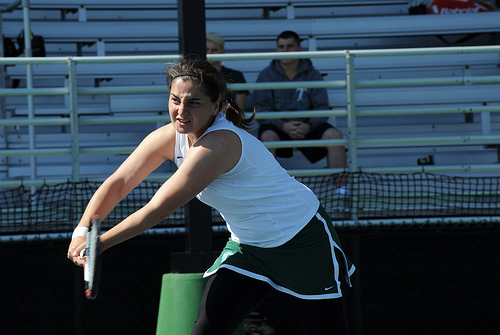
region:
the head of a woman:
[154, 50, 219, 137]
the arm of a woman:
[100, 128, 235, 250]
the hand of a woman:
[63, 225, 94, 265]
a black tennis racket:
[68, 200, 112, 299]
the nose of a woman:
[174, 97, 190, 119]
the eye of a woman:
[168, 92, 183, 106]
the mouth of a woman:
[173, 110, 195, 128]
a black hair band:
[164, 67, 226, 94]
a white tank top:
[169, 110, 329, 252]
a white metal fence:
[1, 40, 498, 225]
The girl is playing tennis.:
[55, 47, 394, 321]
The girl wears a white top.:
[160, 100, 330, 253]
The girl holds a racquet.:
[60, 197, 121, 307]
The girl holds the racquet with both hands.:
[51, 199, 127, 309]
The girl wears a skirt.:
[191, 201, 375, 301]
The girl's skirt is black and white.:
[191, 196, 373, 311]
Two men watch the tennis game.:
[177, 20, 369, 211]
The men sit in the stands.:
[172, 23, 360, 205]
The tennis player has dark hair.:
[147, 52, 279, 123]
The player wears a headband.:
[151, 55, 241, 95]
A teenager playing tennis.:
[25, 42, 395, 329]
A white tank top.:
[160, 120, 332, 260]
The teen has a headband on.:
[150, 47, 255, 147]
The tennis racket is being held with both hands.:
[41, 175, 151, 317]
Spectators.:
[202, 30, 338, 127]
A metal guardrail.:
[2, 40, 494, 205]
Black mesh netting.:
[325, 165, 492, 235]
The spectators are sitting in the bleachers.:
[190, 5, 360, 170]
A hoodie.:
[245, 56, 335, 126]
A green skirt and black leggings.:
[170, 215, 365, 331]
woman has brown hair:
[151, 56, 223, 117]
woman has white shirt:
[196, 116, 321, 256]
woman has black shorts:
[187, 221, 343, 295]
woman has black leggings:
[195, 257, 342, 334]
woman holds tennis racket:
[86, 226, 138, 295]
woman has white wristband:
[66, 217, 93, 252]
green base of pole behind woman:
[140, 224, 215, 331]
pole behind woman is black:
[180, 1, 242, 304]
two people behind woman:
[172, 26, 315, 131]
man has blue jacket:
[254, 51, 346, 113]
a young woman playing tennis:
[68, 35, 374, 325]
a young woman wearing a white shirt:
[40, 99, 362, 314]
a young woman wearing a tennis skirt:
[205, 218, 378, 321]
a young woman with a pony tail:
[147, 45, 249, 159]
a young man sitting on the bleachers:
[251, 31, 368, 171]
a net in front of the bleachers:
[355, 167, 498, 205]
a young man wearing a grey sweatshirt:
[251, 28, 351, 153]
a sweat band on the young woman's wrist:
[60, 206, 141, 277]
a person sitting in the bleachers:
[206, 35, 251, 95]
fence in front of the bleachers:
[347, 51, 492, 160]